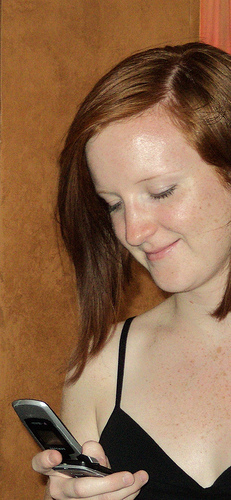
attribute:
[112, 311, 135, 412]
strap — black, camisole, one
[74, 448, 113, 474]
phone — curved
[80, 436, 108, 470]
thumb — one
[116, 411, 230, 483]
shirt — black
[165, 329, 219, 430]
skin — white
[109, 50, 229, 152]
hair — red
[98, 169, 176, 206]
eyebrows — red, thin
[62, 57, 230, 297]
hair — red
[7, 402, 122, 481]
cell phone — silver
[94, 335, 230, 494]
dress — black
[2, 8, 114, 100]
wall — brown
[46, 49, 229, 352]
hair — long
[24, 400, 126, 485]
flip phone — silver, black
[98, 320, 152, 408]
strap — black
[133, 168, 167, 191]
eyebrows — thin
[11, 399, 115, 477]
phone — one, black, silver, flip style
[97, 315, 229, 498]
shirt — black, v-neck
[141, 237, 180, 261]
lips — thin, pink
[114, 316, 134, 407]
strap — spaghetti, black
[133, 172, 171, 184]
eyebrow — reddish brown, thin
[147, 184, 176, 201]
eyelashes — dark, long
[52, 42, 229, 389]
hair — side parted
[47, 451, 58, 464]
fingernail — short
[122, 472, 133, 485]
fingernail — short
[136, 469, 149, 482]
fingernail — short